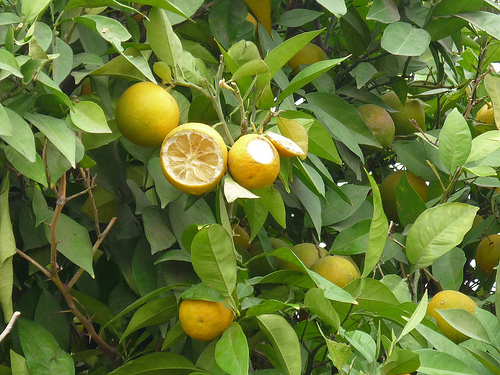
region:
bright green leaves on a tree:
[11, 91, 101, 183]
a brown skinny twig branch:
[11, 213, 71, 263]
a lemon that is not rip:
[105, 63, 175, 138]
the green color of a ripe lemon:
[121, 99, 155, 144]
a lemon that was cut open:
[162, 123, 220, 177]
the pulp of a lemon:
[177, 126, 202, 157]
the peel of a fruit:
[235, 136, 257, 171]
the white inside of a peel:
[248, 145, 272, 162]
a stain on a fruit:
[245, 159, 257, 186]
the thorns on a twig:
[52, 302, 83, 320]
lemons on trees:
[104, 1, 481, 370]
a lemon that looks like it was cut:
[157, 110, 235, 219]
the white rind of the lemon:
[240, 105, 283, 191]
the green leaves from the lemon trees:
[23, 25, 119, 255]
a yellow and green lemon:
[114, 94, 204, 158]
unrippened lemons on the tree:
[285, 34, 477, 256]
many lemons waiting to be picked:
[77, 33, 492, 362]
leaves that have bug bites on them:
[60, 8, 157, 83]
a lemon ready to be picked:
[166, 285, 256, 340]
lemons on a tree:
[106, 67, 310, 236]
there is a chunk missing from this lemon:
[153, 111, 228, 196]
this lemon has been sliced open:
[147, 105, 247, 215]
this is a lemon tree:
[2, 3, 495, 373]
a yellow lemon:
[172, 278, 249, 337]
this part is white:
[243, 119, 282, 186]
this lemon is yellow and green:
[105, 69, 197, 155]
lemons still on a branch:
[93, 58, 364, 219]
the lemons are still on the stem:
[115, 50, 309, 232]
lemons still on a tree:
[102, 36, 318, 201]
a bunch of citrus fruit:
[94, 59, 342, 219]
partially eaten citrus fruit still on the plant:
[228, 125, 333, 220]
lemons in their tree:
[157, 229, 493, 372]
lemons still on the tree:
[22, 22, 498, 361]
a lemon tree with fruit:
[108, 70, 497, 366]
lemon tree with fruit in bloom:
[25, 34, 499, 371]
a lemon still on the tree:
[162, 268, 295, 373]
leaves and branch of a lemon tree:
[8, 100, 116, 336]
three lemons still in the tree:
[285, 234, 475, 369]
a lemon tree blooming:
[8, 15, 498, 357]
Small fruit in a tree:
[108, 81, 181, 143]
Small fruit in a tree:
[150, 105, 224, 204]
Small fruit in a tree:
[168, 283, 240, 363]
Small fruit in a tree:
[285, 233, 330, 275]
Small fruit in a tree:
[306, 248, 370, 307]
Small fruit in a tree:
[415, 272, 485, 343]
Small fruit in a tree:
[449, 219, 499, 267]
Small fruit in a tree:
[365, 158, 442, 236]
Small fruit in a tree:
[340, 91, 399, 157]